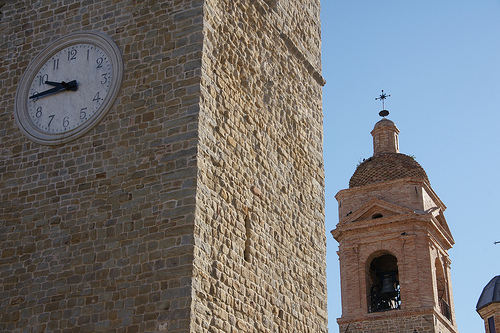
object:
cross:
[376, 88, 392, 121]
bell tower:
[330, 89, 456, 333]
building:
[474, 271, 499, 333]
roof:
[474, 275, 500, 305]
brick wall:
[204, 288, 255, 331]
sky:
[319, 0, 499, 182]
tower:
[330, 77, 462, 333]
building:
[331, 84, 459, 333]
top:
[338, 96, 445, 196]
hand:
[46, 76, 78, 93]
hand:
[30, 84, 79, 101]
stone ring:
[61, 131, 67, 135]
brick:
[0, 0, 326, 333]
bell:
[375, 268, 395, 297]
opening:
[361, 250, 397, 311]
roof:
[350, 153, 424, 182]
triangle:
[352, 204, 399, 225]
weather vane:
[375, 90, 389, 119]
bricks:
[239, 243, 259, 258]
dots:
[86, 46, 89, 48]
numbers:
[59, 44, 78, 65]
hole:
[372, 210, 382, 219]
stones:
[410, 206, 426, 224]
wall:
[342, 180, 440, 329]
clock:
[8, 30, 125, 150]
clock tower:
[2, 1, 329, 328]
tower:
[330, 86, 446, 331]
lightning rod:
[372, 92, 392, 103]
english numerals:
[28, 46, 120, 133]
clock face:
[13, 37, 131, 147]